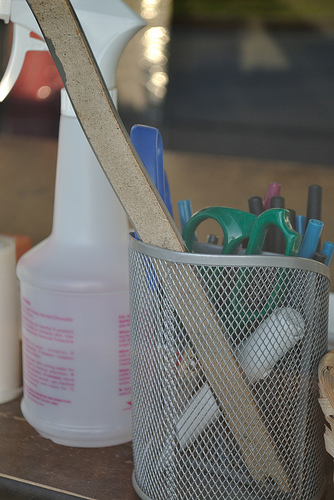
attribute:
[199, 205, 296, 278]
handle — green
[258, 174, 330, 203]
caps — blue, five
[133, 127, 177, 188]
scissors — blue, pair, green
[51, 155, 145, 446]
bottle — clear, cleaner, sitting, spray, plastic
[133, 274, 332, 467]
holder — metal, all purpose, wire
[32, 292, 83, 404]
text — pink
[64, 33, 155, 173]
wood — processed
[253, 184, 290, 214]
cap — pink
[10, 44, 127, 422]
sprayer — plastic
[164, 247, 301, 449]
container — wire, silver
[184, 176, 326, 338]
pens — ball point, topped, black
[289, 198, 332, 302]
pen — held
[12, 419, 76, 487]
desktop — brown